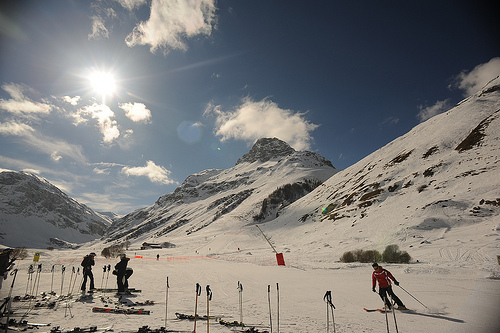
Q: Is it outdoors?
A: Yes, it is outdoors.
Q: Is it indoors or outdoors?
A: It is outdoors.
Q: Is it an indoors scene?
A: No, it is outdoors.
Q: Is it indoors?
A: No, it is outdoors.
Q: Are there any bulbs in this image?
A: No, there are no bulbs.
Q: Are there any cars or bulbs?
A: No, there are no bulbs or cars.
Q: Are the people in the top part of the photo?
A: No, the people are in the bottom of the image.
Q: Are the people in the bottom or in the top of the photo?
A: The people are in the bottom of the image.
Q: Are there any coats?
A: Yes, there is a coat.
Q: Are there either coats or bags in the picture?
A: Yes, there is a coat.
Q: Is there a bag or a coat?
A: Yes, there is a coat.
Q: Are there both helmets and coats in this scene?
A: No, there is a coat but no helmets.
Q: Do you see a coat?
A: Yes, there is a coat.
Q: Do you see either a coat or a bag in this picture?
A: Yes, there is a coat.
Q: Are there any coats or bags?
A: Yes, there is a coat.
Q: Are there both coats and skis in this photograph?
A: Yes, there are both a coat and skis.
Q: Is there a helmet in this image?
A: No, there are no helmets.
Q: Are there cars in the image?
A: No, there are no cars.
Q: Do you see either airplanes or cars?
A: No, there are no cars or airplanes.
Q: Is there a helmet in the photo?
A: No, there are no helmets.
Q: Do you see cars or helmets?
A: No, there are no helmets or cars.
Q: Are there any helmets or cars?
A: No, there are no helmets or cars.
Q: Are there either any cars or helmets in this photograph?
A: No, there are no helmets or cars.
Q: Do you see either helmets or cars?
A: No, there are no helmets or cars.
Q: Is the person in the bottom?
A: Yes, the person is in the bottom of the image.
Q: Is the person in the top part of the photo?
A: No, the person is in the bottom of the image.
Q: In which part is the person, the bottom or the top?
A: The person is in the bottom of the image.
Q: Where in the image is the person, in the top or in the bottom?
A: The person is in the bottom of the image.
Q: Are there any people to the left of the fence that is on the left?
A: Yes, there is a person to the left of the fence.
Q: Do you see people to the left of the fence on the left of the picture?
A: Yes, there is a person to the left of the fence.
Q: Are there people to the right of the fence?
A: No, the person is to the left of the fence.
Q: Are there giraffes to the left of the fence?
A: No, there is a person to the left of the fence.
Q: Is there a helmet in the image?
A: No, there are no helmets.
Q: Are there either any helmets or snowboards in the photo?
A: No, there are no helmets or snowboards.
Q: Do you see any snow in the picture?
A: Yes, there is snow.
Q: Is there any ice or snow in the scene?
A: Yes, there is snow.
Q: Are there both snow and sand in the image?
A: No, there is snow but no sand.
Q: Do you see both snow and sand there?
A: No, there is snow but no sand.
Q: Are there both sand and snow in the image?
A: No, there is snow but no sand.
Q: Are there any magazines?
A: No, there are no magazines.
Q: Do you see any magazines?
A: No, there are no magazines.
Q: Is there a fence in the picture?
A: Yes, there is a fence.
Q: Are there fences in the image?
A: Yes, there is a fence.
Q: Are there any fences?
A: Yes, there is a fence.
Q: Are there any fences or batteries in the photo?
A: Yes, there is a fence.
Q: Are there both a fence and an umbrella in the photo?
A: No, there is a fence but no umbrellas.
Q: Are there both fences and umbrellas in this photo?
A: No, there is a fence but no umbrellas.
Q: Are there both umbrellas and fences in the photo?
A: No, there is a fence but no umbrellas.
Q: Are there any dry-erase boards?
A: No, there are no dry-erase boards.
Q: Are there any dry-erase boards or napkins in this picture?
A: No, there are no dry-erase boards or napkins.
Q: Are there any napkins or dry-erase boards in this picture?
A: No, there are no dry-erase boards or napkins.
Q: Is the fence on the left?
A: Yes, the fence is on the left of the image.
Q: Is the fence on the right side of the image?
A: No, the fence is on the left of the image.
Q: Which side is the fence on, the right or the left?
A: The fence is on the left of the image.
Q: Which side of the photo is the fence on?
A: The fence is on the left of the image.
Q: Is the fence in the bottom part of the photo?
A: Yes, the fence is in the bottom of the image.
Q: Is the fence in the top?
A: No, the fence is in the bottom of the image.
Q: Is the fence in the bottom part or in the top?
A: The fence is in the bottom of the image.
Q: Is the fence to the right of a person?
A: Yes, the fence is to the right of a person.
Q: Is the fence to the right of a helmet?
A: No, the fence is to the right of a person.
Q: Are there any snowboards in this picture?
A: No, there are no snowboards.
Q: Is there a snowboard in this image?
A: No, there are no snowboards.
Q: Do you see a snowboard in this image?
A: No, there are no snowboards.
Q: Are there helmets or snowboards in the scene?
A: No, there are no snowboards or helmets.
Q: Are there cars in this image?
A: No, there are no cars.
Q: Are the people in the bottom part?
A: Yes, the people are in the bottom of the image.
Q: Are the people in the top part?
A: No, the people are in the bottom of the image.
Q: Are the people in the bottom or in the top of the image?
A: The people are in the bottom of the image.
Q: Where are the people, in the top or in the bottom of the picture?
A: The people are in the bottom of the image.